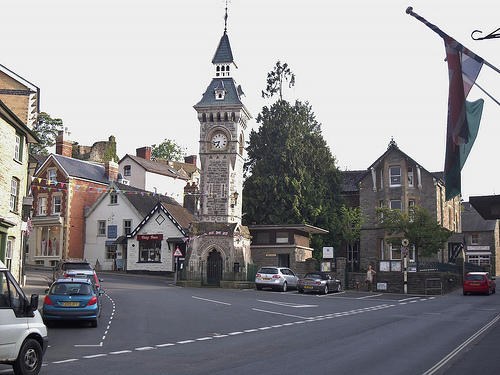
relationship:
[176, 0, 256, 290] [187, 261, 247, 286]
clock tower inside iron fence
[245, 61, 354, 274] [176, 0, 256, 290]
tree behind clock tower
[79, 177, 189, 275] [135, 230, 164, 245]
white building behind red sign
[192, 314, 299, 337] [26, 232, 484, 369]
lines on street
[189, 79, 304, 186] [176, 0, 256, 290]
clock on clock tower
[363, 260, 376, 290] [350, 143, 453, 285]
woman standing next to building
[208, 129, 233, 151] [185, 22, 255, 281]
clock on tower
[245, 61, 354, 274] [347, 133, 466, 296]
tree behind building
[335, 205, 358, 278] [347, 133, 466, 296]
tree behind building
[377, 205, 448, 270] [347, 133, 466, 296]
tree behind building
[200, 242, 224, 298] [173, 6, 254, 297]
door of tower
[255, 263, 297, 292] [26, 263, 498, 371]
car parked on street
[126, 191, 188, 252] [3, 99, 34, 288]
triangles hanging from building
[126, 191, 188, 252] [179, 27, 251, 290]
triangles hanging from tower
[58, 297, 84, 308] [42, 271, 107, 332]
license on car